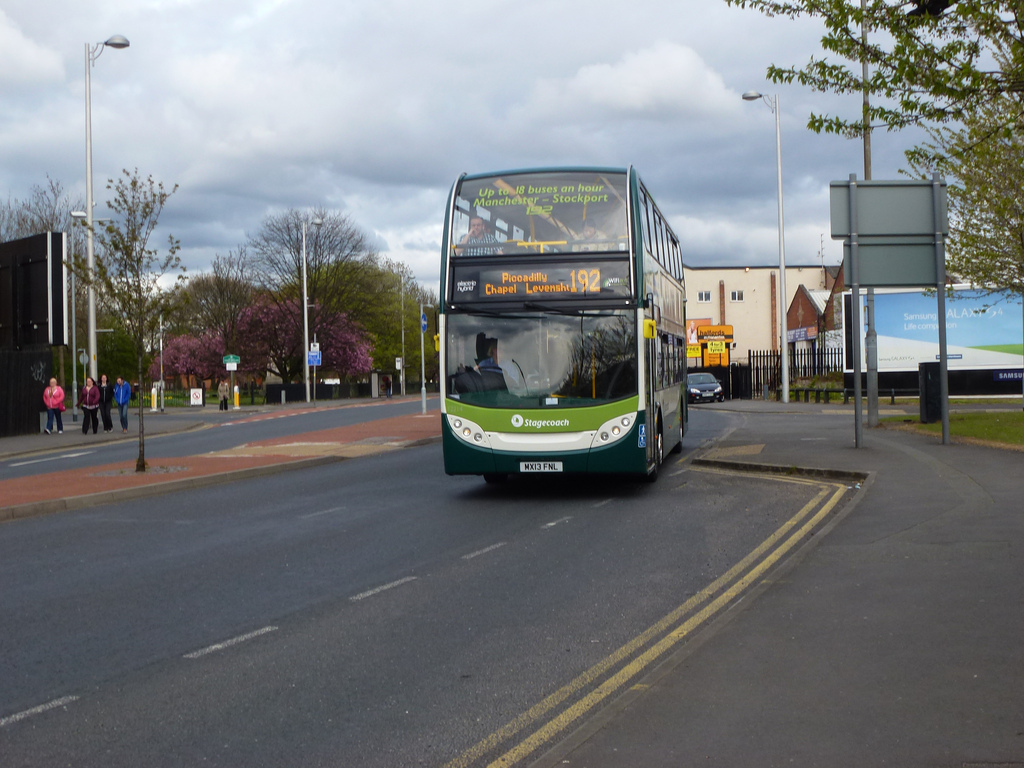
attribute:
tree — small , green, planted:
[87, 208, 194, 459]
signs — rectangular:
[839, 165, 943, 330]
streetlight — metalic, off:
[263, 201, 339, 411]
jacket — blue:
[105, 368, 138, 412]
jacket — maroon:
[68, 376, 103, 409]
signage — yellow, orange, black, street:
[677, 309, 744, 389]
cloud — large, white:
[524, 70, 708, 127]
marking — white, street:
[317, 521, 497, 591]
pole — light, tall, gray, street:
[725, 63, 806, 420]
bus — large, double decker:
[422, 145, 680, 496]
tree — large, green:
[271, 206, 403, 416]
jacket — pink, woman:
[40, 387, 62, 418]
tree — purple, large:
[146, 310, 222, 399]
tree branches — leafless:
[214, 207, 398, 393]